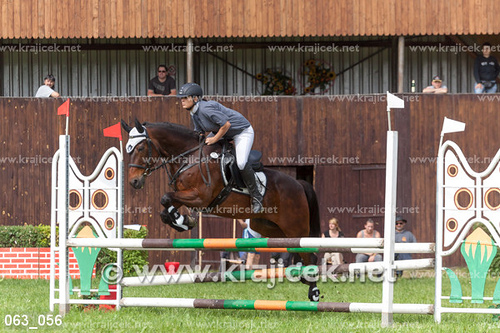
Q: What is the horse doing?
A: Jumping.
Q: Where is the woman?
A: On the horse.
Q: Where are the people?
A: By the fence.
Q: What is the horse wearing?
A: A saddle.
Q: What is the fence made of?
A: Wood.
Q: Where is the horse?
A: By the rail.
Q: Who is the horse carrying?
A: The woman.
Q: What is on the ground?
A: Green grass.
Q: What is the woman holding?
A: The rein.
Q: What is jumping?
A: Horse.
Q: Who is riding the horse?
A: Jockey.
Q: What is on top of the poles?
A: Flags.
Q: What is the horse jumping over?
A: A hurdle.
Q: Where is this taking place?
A: A competition.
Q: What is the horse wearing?
A: A saddle.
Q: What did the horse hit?
A: A hurdle.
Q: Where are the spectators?
A: In the stands.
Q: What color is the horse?
A: Brown.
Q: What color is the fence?
A: Light brown.